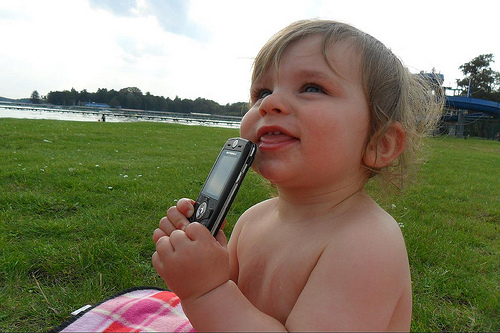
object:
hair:
[252, 19, 446, 195]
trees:
[30, 87, 250, 117]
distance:
[0, 87, 252, 130]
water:
[0, 106, 242, 129]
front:
[0, 107, 241, 129]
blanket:
[58, 286, 194, 332]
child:
[151, 20, 412, 333]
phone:
[186, 137, 258, 239]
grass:
[8, 135, 146, 279]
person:
[101, 113, 105, 122]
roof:
[85, 103, 111, 107]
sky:
[0, 0, 499, 108]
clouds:
[0, 0, 219, 69]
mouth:
[254, 125, 301, 151]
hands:
[151, 197, 230, 301]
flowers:
[32, 133, 165, 213]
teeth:
[267, 132, 280, 136]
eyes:
[254, 82, 330, 99]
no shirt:
[185, 193, 414, 332]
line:
[0, 100, 246, 125]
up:
[240, 44, 370, 183]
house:
[85, 103, 111, 108]